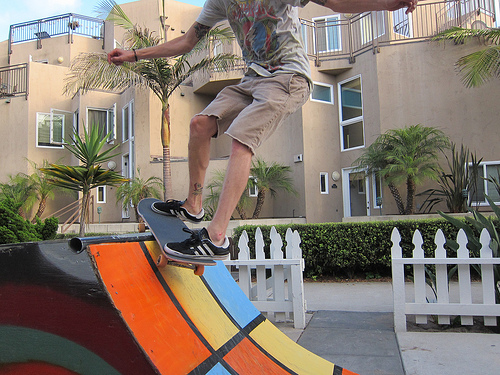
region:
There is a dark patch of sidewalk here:
[331, 318, 365, 367]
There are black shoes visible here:
[191, 223, 215, 257]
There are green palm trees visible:
[391, 145, 417, 212]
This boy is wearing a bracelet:
[123, 38, 140, 66]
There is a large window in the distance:
[343, 78, 365, 149]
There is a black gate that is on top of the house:
[33, 19, 43, 40]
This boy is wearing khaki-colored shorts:
[227, 124, 264, 194]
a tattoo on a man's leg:
[190, 178, 205, 199]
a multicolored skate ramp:
[87, 223, 398, 374]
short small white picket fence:
[208, 228, 498, 324]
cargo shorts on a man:
[195, 68, 306, 148]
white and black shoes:
[153, 188, 233, 265]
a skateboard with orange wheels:
[130, 186, 217, 281]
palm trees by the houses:
[8, 5, 498, 261]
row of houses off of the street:
[7, 5, 499, 261]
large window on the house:
[336, 69, 371, 153]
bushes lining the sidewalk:
[202, 213, 498, 288]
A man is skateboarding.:
[106, 0, 424, 273]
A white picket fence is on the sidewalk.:
[390, 228, 499, 330]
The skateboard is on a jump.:
[0, 197, 352, 374]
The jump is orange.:
[135, 298, 171, 334]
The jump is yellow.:
[193, 295, 210, 322]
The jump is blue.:
[224, 289, 244, 308]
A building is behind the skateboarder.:
[322, 27, 434, 121]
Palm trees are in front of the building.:
[42, 120, 123, 194]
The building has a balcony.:
[310, 16, 367, 61]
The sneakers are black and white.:
[163, 228, 232, 259]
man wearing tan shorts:
[250, 103, 270, 123]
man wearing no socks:
[211, 226, 224, 238]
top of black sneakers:
[173, 241, 188, 250]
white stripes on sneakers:
[195, 246, 212, 258]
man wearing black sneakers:
[150, 187, 200, 266]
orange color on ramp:
[108, 278, 148, 302]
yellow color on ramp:
[191, 295, 212, 318]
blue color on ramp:
[220, 285, 242, 304]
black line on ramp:
[227, 338, 238, 348]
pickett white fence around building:
[404, 249, 469, 296]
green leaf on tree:
[62, 132, 94, 164]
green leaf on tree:
[83, 151, 100, 179]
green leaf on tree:
[25, 203, 57, 231]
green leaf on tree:
[9, 211, 16, 238]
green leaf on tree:
[389, 130, 404, 152]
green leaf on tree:
[376, 153, 410, 176]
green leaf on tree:
[407, 138, 434, 190]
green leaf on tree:
[349, 227, 365, 244]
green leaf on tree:
[314, 245, 339, 271]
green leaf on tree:
[453, 177, 477, 204]